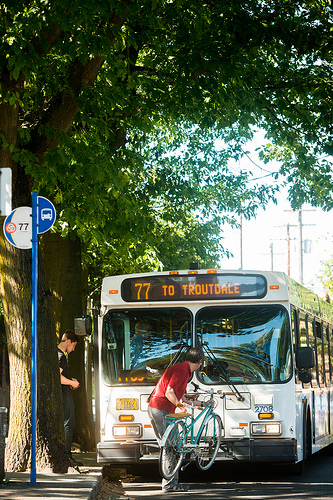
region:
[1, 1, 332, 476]
tall overhanging shade trees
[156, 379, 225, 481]
turquoise and white man's bicycle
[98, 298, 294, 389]
glass bus windows reflecting the light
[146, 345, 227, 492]
man putting a bicycle on a bus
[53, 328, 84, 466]
young man standing and looking down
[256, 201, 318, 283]
three telephone poles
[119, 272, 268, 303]
direction light indicating bus number and destination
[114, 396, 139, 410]
yellow front license plate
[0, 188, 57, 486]
blue and white bus stop sign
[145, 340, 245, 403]
pair of windshield wipers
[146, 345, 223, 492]
Man putting his bike on a bike rack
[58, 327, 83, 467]
Man wearing a black shirt and gray pants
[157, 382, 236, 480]
Bicycle with light blue frame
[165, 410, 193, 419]
Wood bicycle seat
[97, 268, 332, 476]
White mass transit bus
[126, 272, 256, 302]
Digital route sign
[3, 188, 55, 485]
Two bus signs on a blue pole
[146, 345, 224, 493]
Man lifting up his bicycle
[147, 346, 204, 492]
Man wearing a red shirt and grey pants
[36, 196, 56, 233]
Blue half circle bus sign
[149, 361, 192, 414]
the man is wearing a short sleeve shirt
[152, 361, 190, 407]
the shirt is red in color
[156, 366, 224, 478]
the man is holding a bicycle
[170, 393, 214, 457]
the bicycle is blue in color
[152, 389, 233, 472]
the bicycle is off the ground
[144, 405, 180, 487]
the man is wearing long pants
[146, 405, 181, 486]
the pants are grey in color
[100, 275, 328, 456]
the bus is white in color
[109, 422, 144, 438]
a headlight is on the front of the bus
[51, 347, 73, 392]
the man is wearing a short sleeve shirt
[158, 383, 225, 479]
a blue bike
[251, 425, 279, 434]
a bus headlight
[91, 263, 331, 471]
part of a large bus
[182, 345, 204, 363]
a man's short cut hair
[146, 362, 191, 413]
a man's short sleeve shirt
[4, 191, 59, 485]
a tall blue pole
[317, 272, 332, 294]
green tree leaves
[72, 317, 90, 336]
a large side mirror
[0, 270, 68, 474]
part of a large tree trunk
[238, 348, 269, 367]
part of a large steering wheel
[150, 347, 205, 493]
man wearing red shirt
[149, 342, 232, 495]
man holding bike in front of bus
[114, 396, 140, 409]
yellow license plate on front of bus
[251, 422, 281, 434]
headlights on front of bus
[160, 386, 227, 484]
blue bike in front of bus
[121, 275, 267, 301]
bus route on front of bus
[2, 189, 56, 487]
blue bus route sign on street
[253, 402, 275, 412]
bus ID number on front of bus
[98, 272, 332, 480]
public transportation bus at stop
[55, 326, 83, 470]
man standing at bus stop